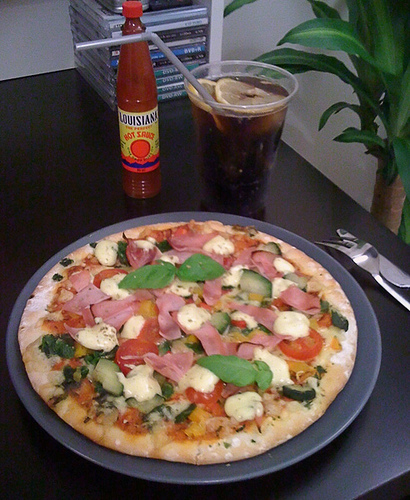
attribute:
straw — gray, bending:
[75, 31, 220, 116]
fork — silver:
[313, 234, 408, 316]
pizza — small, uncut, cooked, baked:
[19, 219, 356, 469]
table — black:
[1, 71, 408, 500]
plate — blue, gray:
[7, 213, 383, 486]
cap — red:
[121, 1, 144, 20]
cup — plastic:
[185, 62, 299, 217]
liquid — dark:
[194, 73, 286, 213]